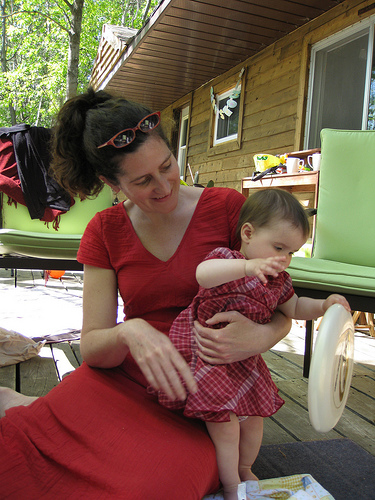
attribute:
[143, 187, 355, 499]
baby — barefoot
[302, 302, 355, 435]
frisbee — white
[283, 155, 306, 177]
mug — white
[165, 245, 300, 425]
red plaid dress — white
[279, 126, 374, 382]
chair — green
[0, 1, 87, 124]
tree — green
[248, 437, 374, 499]
mat — gray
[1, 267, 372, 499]
deck — wood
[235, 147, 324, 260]
table — wood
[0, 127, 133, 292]
back chair — green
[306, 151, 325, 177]
mug — white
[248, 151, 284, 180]
bowl — yellow